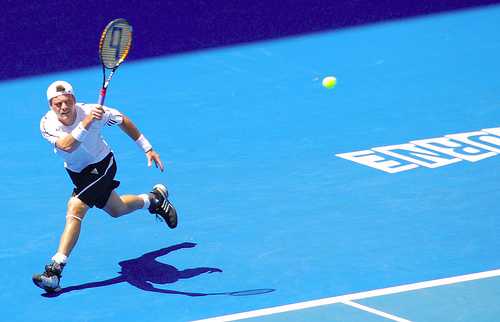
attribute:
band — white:
[132, 132, 152, 152]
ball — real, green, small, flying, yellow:
[321, 76, 339, 88]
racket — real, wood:
[98, 17, 133, 107]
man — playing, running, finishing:
[32, 81, 178, 294]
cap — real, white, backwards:
[48, 78, 76, 101]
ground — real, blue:
[223, 199, 251, 216]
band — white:
[137, 133, 153, 156]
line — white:
[346, 298, 411, 321]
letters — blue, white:
[334, 122, 499, 174]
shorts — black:
[67, 152, 122, 208]